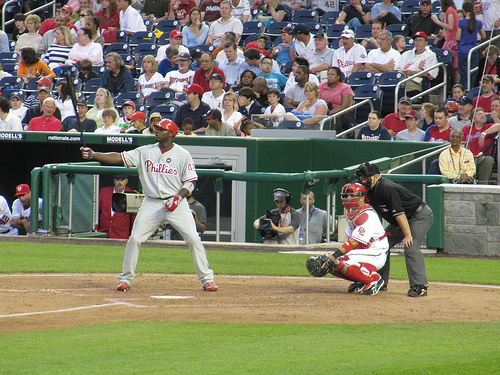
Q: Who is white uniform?
A: Baseball player.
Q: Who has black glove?
A: Catcher.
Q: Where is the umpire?
A: Behind catcher.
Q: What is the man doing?
A: Playing tennis.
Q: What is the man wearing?
A: Uniform.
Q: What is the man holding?
A: A bat.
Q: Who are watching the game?
A: Fans.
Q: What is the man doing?
A: Squatting.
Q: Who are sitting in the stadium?
A: Fans.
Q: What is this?
A: A batting scene.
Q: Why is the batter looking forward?
A: To see the pitch.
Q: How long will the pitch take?
A: A few seconds.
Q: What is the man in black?
A: The umpire.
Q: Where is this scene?
A: The baseball diamond.